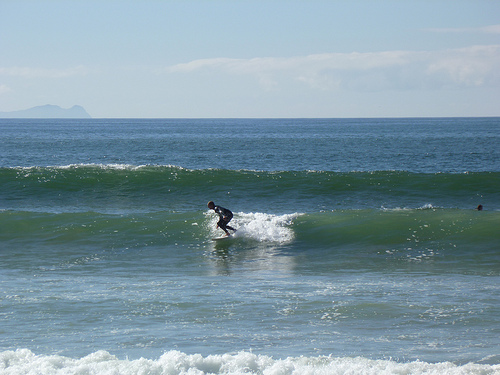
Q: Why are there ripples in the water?
A: Wave.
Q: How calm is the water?
A: Slightly.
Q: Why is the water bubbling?
A: Hitting the shore.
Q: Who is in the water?
A: No one.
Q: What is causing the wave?
A: Gravity.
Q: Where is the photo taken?
A: The ocean.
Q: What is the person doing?
A: Surfing.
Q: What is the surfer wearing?
A: A wetsuit.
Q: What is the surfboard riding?
A: A wave.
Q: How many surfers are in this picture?
A: One.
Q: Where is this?
A: Near a beach.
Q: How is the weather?
A: Mostly clear.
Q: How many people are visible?
A: 1.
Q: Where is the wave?
A: Behind the surfer.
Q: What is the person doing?
A: Surfing.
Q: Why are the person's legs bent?
A: For balance.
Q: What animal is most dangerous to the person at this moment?
A: Sharks.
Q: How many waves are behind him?
A: Two.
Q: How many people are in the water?
A: Two.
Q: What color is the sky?
A: Blue.